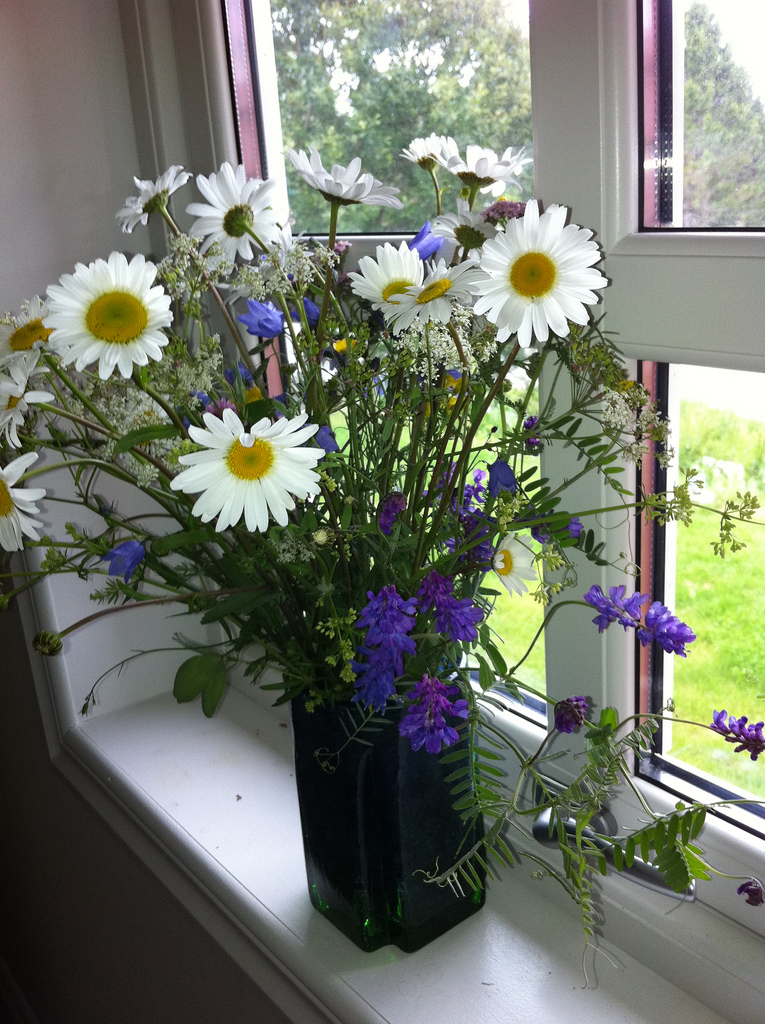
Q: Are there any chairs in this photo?
A: No, there are no chairs.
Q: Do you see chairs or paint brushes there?
A: No, there are no chairs or paint brushes.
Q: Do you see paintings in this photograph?
A: No, there are no paintings.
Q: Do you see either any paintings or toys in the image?
A: No, there are no paintings or toys.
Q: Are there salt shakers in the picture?
A: No, there are no salt shakers.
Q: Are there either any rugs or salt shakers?
A: No, there are no salt shakers or rugs.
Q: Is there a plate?
A: No, there are no plates.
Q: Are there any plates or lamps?
A: No, there are no plates or lamps.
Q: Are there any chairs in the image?
A: No, there are no chairs.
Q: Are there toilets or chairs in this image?
A: No, there are no chairs or toilets.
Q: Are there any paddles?
A: No, there are no paddles.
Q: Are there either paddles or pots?
A: No, there are no paddles or pots.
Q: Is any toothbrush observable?
A: No, there are no toothbrushes.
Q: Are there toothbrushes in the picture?
A: No, there are no toothbrushes.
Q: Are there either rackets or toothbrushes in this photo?
A: No, there are no toothbrushes or rackets.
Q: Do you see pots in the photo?
A: No, there are no pots.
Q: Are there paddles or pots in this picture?
A: No, there are no pots or paddles.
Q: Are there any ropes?
A: No, there are no ropes.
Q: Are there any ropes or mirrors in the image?
A: No, there are no ropes or mirrors.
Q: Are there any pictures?
A: No, there are no pictures.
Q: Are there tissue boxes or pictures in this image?
A: No, there are no pictures or tissue boxes.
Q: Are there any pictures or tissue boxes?
A: No, there are no pictures or tissue boxes.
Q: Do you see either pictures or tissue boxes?
A: No, there are no pictures or tissue boxes.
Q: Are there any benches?
A: No, there are no benches.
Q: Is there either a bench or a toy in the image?
A: No, there are no benches or toys.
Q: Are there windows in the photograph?
A: Yes, there is a window.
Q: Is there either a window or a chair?
A: Yes, there is a window.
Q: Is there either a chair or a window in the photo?
A: Yes, there is a window.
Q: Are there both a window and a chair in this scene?
A: No, there is a window but no chairs.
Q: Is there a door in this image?
A: No, there are no doors.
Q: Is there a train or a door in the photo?
A: No, there are no doors or trains.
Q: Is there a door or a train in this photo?
A: No, there are no doors or trains.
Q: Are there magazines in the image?
A: No, there are no magazines.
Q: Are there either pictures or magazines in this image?
A: No, there are no magazines or pictures.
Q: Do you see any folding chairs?
A: No, there are no folding chairs.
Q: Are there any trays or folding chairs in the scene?
A: No, there are no folding chairs or trays.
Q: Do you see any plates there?
A: No, there are no plates.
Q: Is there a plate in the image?
A: No, there are no plates.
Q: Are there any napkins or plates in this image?
A: No, there are no plates or napkins.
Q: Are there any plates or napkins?
A: No, there are no plates or napkins.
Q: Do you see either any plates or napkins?
A: No, there are no plates or napkins.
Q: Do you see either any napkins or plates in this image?
A: No, there are no plates or napkins.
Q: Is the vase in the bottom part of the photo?
A: Yes, the vase is in the bottom of the image.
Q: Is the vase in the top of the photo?
A: No, the vase is in the bottom of the image.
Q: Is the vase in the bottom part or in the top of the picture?
A: The vase is in the bottom of the image.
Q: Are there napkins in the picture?
A: No, there are no napkins.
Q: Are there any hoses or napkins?
A: No, there are no napkins or hoses.